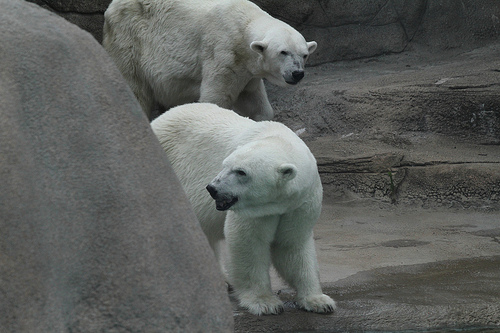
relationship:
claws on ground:
[233, 274, 357, 316] [342, 191, 494, 328]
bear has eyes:
[160, 109, 340, 315] [232, 163, 252, 183]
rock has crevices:
[3, 26, 169, 332] [324, 89, 499, 136]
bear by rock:
[160, 109, 340, 315] [3, 26, 169, 332]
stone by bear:
[294, 96, 355, 155] [160, 109, 340, 315]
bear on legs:
[160, 109, 340, 315] [146, 83, 278, 124]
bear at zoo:
[160, 109, 340, 315] [4, 8, 497, 312]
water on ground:
[379, 309, 494, 331] [342, 191, 494, 328]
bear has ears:
[160, 109, 340, 315] [247, 37, 276, 63]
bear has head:
[160, 109, 340, 315] [251, 26, 316, 89]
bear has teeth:
[160, 109, 340, 315] [215, 197, 235, 208]